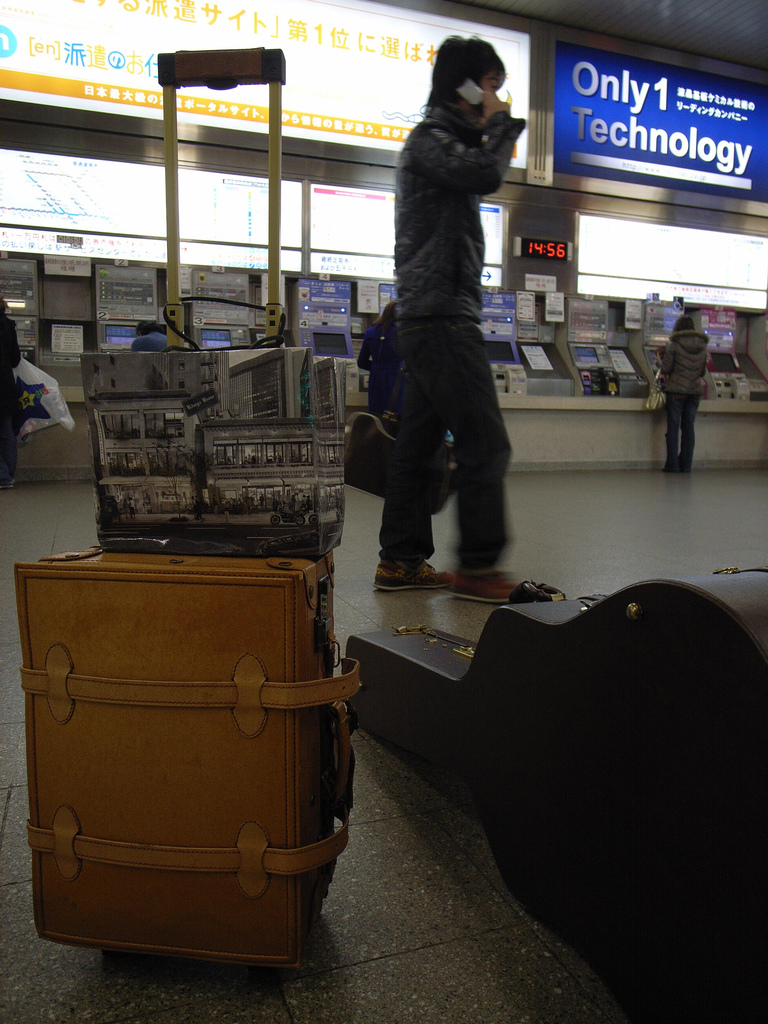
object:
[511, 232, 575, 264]
clock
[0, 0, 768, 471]
wall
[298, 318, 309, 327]
number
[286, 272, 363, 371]
kiosk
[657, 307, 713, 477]
person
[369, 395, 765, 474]
counter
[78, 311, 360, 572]
bag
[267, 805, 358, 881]
straps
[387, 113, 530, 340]
coat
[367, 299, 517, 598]
jeans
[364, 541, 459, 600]
shoes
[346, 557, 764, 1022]
case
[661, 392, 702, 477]
jeans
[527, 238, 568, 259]
time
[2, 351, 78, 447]
bag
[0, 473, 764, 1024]
floor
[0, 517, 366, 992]
suitcase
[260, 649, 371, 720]
strap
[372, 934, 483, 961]
crack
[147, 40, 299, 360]
handle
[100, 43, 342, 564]
carrier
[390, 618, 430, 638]
clasp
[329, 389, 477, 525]
case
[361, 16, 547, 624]
man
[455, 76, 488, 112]
cellphone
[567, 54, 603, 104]
letter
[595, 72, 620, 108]
letter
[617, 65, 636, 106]
letter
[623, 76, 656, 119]
letter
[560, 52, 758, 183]
sign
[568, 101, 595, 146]
letter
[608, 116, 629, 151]
letter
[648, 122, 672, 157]
letter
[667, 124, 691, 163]
letter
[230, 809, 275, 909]
handle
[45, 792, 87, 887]
handle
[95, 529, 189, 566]
handle